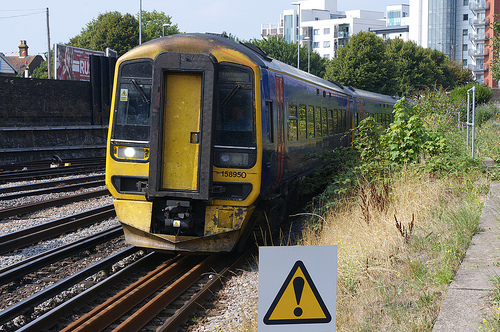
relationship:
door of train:
[155, 67, 204, 191] [105, 31, 420, 258]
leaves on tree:
[144, 10, 172, 27] [142, 9, 172, 41]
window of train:
[263, 95, 281, 146] [85, 16, 482, 264]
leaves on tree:
[338, 33, 466, 79] [325, 41, 452, 72]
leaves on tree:
[314, 40, 476, 83] [322, 36, 422, 85]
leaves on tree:
[362, 114, 484, 191] [355, 80, 465, 208]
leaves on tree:
[330, 40, 436, 89] [324, 33, 461, 92]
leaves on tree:
[261, 28, 435, 92] [262, 30, 346, 69]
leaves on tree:
[251, 20, 341, 71] [240, 16, 381, 84]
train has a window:
[69, 36, 448, 272] [204, 52, 274, 165]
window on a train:
[105, 33, 165, 158] [85, 16, 482, 264]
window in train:
[294, 93, 333, 154] [96, 62, 477, 261]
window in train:
[319, 92, 365, 144] [56, 28, 466, 257]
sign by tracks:
[242, 223, 353, 327] [0, 106, 298, 326]